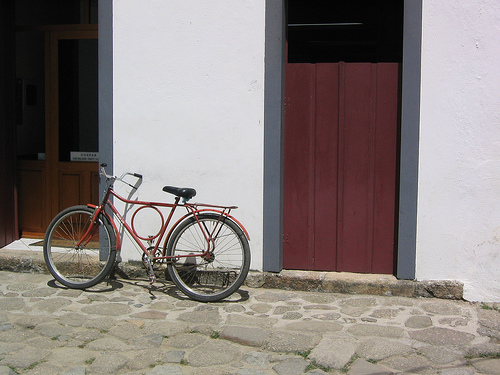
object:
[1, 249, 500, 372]
ground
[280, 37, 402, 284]
lines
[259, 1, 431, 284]
door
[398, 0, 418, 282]
edges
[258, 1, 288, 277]
edges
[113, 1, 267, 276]
walls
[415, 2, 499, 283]
walls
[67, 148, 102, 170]
plate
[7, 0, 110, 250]
door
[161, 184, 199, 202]
seat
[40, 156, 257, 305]
bike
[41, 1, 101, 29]
space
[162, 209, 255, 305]
tire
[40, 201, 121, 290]
tire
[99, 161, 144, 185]
bars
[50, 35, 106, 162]
glass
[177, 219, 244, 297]
spokes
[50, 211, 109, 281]
spokes